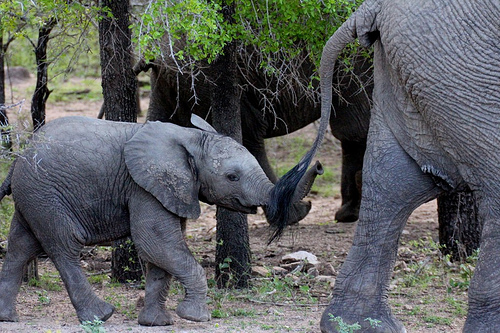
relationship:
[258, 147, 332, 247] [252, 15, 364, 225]
hair on end of tail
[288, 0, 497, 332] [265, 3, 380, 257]
elephant has tail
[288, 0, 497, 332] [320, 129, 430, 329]
elephant has leg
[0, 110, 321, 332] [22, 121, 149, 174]
elephant has back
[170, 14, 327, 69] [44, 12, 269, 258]
leaves on trees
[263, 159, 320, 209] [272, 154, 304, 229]
trunk underneath hair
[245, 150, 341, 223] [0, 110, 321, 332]
elephant trunk underneath elephant